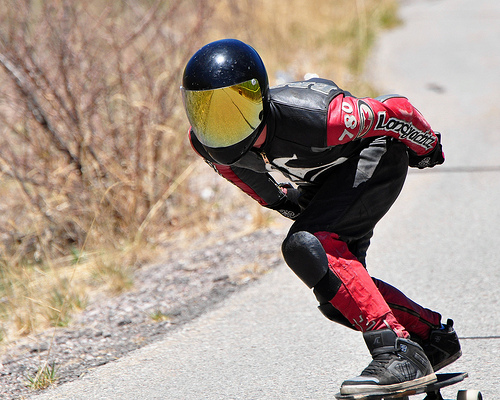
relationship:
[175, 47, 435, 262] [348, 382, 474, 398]
man on skateboard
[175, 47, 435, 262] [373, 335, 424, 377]
man wearing shoes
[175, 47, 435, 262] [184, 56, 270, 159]
man wearing helmet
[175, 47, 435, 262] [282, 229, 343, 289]
man wearing knee pads